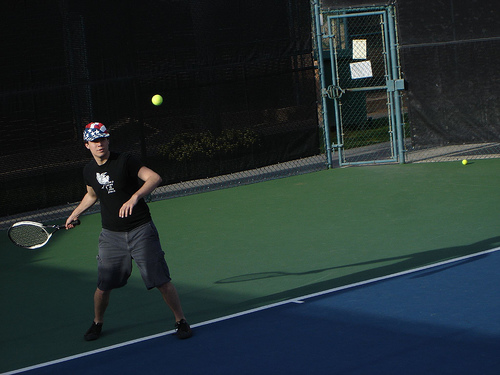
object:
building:
[0, 0, 500, 235]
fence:
[1, 0, 497, 233]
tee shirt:
[81, 157, 148, 233]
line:
[202, 243, 497, 322]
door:
[313, 6, 407, 169]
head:
[84, 121, 111, 157]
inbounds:
[4, 245, 499, 373]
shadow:
[214, 234, 500, 299]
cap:
[82, 121, 111, 143]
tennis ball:
[151, 93, 164, 106]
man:
[54, 121, 197, 339]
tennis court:
[0, 162, 497, 374]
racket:
[0, 217, 84, 253]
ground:
[0, 156, 500, 374]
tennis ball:
[461, 159, 468, 165]